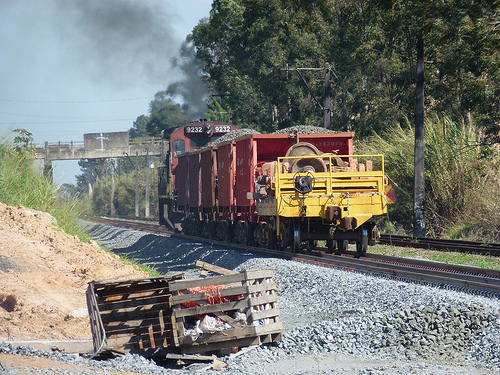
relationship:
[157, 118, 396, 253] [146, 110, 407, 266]
car forming train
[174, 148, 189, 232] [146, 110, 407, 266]
car forming train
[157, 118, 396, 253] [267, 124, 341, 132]
car filled with gravel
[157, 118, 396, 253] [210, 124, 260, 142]
car filled with gravel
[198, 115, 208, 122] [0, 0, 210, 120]
smoke stack emitting smoke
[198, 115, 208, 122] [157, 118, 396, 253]
smoke stack built into car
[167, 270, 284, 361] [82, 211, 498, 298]
crate lying next to train tracks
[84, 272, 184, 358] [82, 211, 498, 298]
crate lying next to train tracks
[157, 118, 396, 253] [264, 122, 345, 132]
car filled with gravel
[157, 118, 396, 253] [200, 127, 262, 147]
car filled with gravel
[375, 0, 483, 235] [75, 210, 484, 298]
tree standing alongside train track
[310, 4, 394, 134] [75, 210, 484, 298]
tree standing alongside train track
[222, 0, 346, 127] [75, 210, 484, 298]
tree standing alongside train track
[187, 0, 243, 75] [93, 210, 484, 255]
tree standing alongside train track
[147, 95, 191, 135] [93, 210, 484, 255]
tree standing alongside train track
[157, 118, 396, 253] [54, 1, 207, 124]
car emitting smoke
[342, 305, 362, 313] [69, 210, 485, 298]
rock lying next to track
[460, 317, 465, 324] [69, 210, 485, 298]
rock lying next to track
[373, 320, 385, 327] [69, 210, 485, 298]
rock lying next to track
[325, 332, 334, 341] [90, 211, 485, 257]
rock lying next to track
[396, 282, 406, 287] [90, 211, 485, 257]
rock lying next to track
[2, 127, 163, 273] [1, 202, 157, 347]
grass sitting dirt mound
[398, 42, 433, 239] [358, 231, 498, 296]
trunk next to tracks